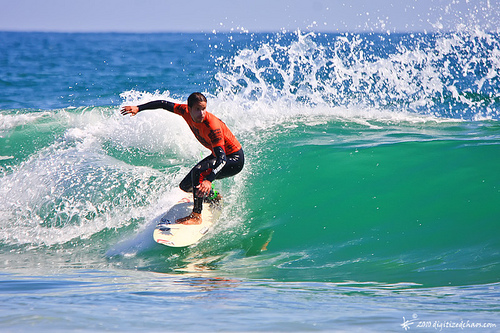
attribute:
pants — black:
[173, 142, 243, 222]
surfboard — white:
[150, 191, 217, 248]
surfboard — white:
[150, 172, 226, 248]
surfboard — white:
[128, 181, 237, 268]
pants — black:
[177, 144, 245, 214]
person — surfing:
[136, 93, 239, 227]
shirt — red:
[174, 102, 240, 161]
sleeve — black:
[207, 149, 229, 180]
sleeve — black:
[134, 99, 173, 113]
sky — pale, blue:
[1, 3, 497, 49]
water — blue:
[66, 35, 161, 102]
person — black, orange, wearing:
[120, 85, 247, 224]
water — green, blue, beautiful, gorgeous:
[2, 30, 498, 330]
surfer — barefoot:
[119, 90, 247, 227]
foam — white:
[220, 5, 499, 115]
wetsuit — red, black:
[134, 88, 236, 201]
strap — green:
[205, 186, 219, 203]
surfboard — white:
[114, 172, 238, 256]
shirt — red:
[168, 88, 270, 157]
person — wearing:
[133, 84, 249, 241]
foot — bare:
[177, 208, 202, 225]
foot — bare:
[203, 192, 222, 207]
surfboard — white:
[134, 180, 261, 258]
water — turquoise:
[1, 106, 497, 291]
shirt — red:
[168, 101, 243, 159]